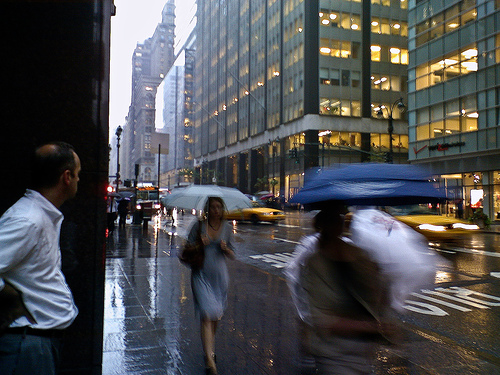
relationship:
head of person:
[307, 205, 354, 241] [298, 203, 388, 365]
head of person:
[19, 136, 94, 207] [3, 133, 123, 372]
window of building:
[318, 99, 365, 117] [0, 0, 499, 374]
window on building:
[442, 114, 469, 138] [395, 28, 496, 168]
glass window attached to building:
[414, 40, 478, 92] [405, 4, 497, 164]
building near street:
[0, 0, 499, 374] [95, 104, 496, 373]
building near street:
[154, 36, 209, 203] [95, 104, 496, 373]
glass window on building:
[460, 44, 480, 76] [401, 0, 499, 211]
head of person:
[200, 197, 228, 221] [188, 194, 238, 368]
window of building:
[317, 40, 352, 58] [0, 0, 499, 374]